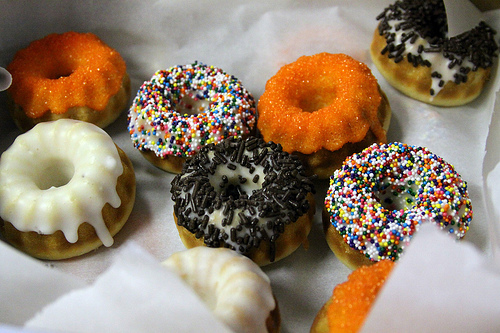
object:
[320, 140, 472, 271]
donuts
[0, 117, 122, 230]
topping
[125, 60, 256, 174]
donut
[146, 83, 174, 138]
confetti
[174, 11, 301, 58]
paper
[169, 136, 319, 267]
donut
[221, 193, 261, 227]
chocolate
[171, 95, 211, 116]
center hole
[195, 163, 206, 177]
part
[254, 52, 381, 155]
toppings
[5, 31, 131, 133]
doughnut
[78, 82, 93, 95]
orange frosting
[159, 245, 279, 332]
doughnut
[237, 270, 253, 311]
white frosting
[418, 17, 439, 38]
chocolate sprinkles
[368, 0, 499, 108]
doughnut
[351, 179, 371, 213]
rainbow sprinkles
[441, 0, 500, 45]
white paper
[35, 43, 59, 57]
orange icing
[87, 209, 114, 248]
white icing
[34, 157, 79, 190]
hole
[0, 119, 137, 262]
doughnut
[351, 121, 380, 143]
ridges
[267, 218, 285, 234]
edge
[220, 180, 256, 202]
hole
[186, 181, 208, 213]
black sprinkles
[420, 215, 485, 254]
edge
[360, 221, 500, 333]
white paper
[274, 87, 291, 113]
frosting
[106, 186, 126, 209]
frosting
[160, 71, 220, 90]
sprinkles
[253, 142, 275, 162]
sprinkles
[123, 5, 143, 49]
nonparells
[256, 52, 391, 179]
donut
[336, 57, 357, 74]
orange toppings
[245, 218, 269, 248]
dark sprinkles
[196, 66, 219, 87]
colorful sprinkles